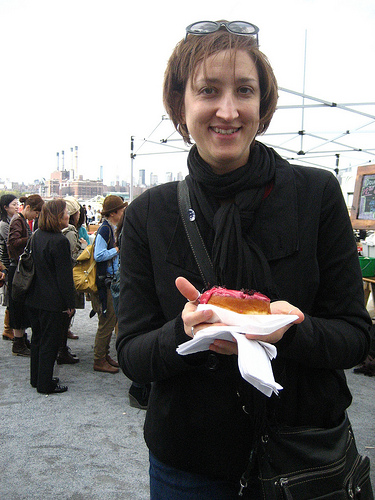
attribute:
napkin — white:
[135, 308, 317, 399]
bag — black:
[223, 395, 372, 498]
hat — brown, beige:
[96, 198, 113, 219]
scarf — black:
[164, 150, 282, 253]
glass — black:
[186, 5, 267, 44]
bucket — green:
[350, 250, 371, 276]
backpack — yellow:
[53, 235, 97, 305]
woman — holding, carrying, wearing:
[86, 13, 371, 457]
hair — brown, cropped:
[147, 57, 202, 100]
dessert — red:
[198, 283, 278, 317]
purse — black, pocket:
[267, 402, 357, 483]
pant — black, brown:
[5, 305, 106, 390]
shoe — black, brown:
[13, 362, 82, 409]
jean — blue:
[143, 443, 238, 499]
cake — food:
[206, 256, 291, 318]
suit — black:
[121, 151, 346, 422]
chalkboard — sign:
[343, 165, 366, 235]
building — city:
[2, 158, 152, 219]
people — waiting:
[2, 163, 188, 394]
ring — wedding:
[170, 290, 211, 338]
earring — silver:
[161, 110, 195, 153]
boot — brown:
[91, 347, 149, 368]